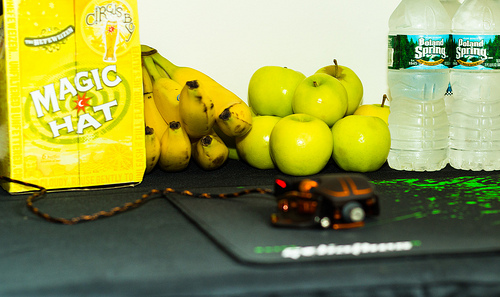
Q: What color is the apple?
A: Green.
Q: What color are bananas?
A: Yellow.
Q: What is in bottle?
A: Water.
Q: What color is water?
A: Clear.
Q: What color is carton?
A: Yellow.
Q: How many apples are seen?
A: Seven.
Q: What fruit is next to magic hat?
A: Bananas.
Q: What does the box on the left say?
A: Magic Hat.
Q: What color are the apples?
A: Green.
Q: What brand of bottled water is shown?
A: Poland spring.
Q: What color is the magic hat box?
A: Yellow.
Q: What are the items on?
A: Table.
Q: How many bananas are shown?
A: Five.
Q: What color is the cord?
A: Orange and black.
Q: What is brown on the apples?
A: Stem.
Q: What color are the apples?
A: Green.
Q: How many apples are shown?
A: 7.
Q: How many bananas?
A: 5.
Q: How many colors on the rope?
A: 2.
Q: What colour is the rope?
A: Orange and black.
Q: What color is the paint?
A: Green.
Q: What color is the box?
A: Yellow.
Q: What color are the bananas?
A: Yellow.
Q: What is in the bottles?
A: Water.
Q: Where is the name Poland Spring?
A: On bottles.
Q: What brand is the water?
A: Poland Spring.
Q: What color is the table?
A: Black.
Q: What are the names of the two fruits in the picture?
A: Banana and apple.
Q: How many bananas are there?
A: 5.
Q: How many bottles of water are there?
A: Two.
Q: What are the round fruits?
A: Apples.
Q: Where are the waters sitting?
A: On the counter.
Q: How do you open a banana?
A: Peel it.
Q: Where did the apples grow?
A: On a tree.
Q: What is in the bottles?
A: Water.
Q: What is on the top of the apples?
A: Stems.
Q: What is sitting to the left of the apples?
A: Bananas.